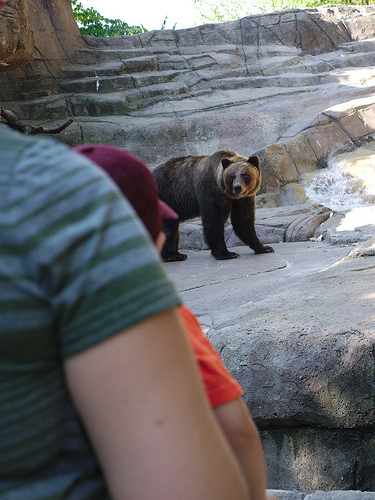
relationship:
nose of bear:
[230, 181, 242, 196] [147, 147, 276, 263]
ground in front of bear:
[157, 240, 373, 390] [147, 147, 276, 263]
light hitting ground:
[333, 190, 369, 243] [254, 252, 325, 295]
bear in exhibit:
[147, 146, 275, 263] [4, 0, 370, 157]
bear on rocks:
[147, 146, 275, 263] [18, 4, 373, 497]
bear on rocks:
[147, 147, 276, 263] [154, 242, 354, 313]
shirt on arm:
[0, 125, 184, 500] [172, 302, 272, 498]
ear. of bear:
[247, 154, 264, 168] [147, 146, 275, 263]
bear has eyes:
[147, 146, 275, 263] [220, 169, 259, 184]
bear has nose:
[147, 146, 275, 263] [230, 173, 254, 192]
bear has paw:
[147, 146, 275, 263] [253, 243, 274, 254]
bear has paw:
[147, 146, 275, 263] [212, 251, 239, 259]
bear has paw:
[147, 146, 275, 263] [161, 253, 188, 260]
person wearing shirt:
[1, 126, 249, 492] [4, 123, 184, 498]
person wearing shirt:
[1, 126, 249, 492] [67, 144, 266, 498]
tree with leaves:
[72, 1, 180, 36] [96, 13, 122, 27]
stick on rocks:
[98, 37, 257, 71] [320, 132, 360, 166]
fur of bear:
[171, 160, 212, 203] [149, 145, 270, 277]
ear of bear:
[246, 152, 263, 168] [147, 146, 275, 263]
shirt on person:
[0, 125, 184, 500] [1, 126, 249, 492]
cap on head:
[75, 144, 184, 230] [67, 138, 181, 288]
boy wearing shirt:
[73, 140, 247, 407] [161, 277, 253, 414]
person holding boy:
[1, 126, 249, 492] [62, 138, 271, 499]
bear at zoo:
[147, 147, 276, 263] [2, 0, 362, 499]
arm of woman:
[50, 177, 253, 500] [1, 119, 264, 499]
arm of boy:
[213, 385, 268, 498] [62, 138, 271, 499]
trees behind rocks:
[70, 1, 373, 33] [4, 3, 359, 220]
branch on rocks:
[0, 104, 77, 138] [75, 18, 223, 164]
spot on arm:
[157, 412, 171, 430] [32, 136, 248, 498]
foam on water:
[305, 159, 363, 213] [304, 148, 374, 212]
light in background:
[109, 9, 180, 32] [75, 7, 340, 67]